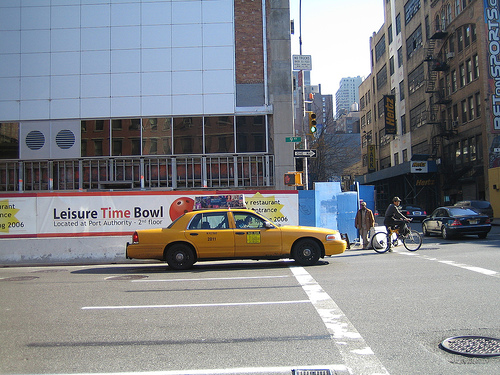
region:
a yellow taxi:
[125, 206, 346, 266]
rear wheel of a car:
[161, 242, 193, 268]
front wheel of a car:
[291, 238, 321, 266]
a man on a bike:
[374, 198, 423, 251]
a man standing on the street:
[352, 201, 374, 246]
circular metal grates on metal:
[19, 120, 80, 158]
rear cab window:
[190, 212, 228, 232]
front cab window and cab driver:
[230, 211, 265, 232]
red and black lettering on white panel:
[50, 206, 162, 228]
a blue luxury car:
[420, 207, 491, 242]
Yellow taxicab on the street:
[122, 205, 347, 271]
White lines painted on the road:
[71, 265, 386, 365]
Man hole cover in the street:
[413, 315, 498, 370]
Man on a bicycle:
[368, 195, 423, 252]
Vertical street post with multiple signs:
[281, 52, 318, 192]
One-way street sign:
[290, 144, 318, 191]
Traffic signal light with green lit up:
[298, 91, 325, 148]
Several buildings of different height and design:
[313, 1, 412, 177]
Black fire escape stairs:
[419, 14, 459, 168]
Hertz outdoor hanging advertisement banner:
[374, 85, 404, 145]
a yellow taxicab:
[115, 199, 380, 273]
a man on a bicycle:
[368, 188, 439, 261]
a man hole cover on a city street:
[434, 315, 499, 362]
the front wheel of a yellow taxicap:
[287, 235, 330, 272]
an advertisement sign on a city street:
[0, 187, 342, 250]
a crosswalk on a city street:
[285, 215, 490, 373]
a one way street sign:
[290, 145, 325, 164]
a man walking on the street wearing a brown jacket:
[350, 197, 375, 259]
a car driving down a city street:
[420, 202, 497, 264]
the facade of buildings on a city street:
[338, 2, 495, 205]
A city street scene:
[6, 0, 498, 362]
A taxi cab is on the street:
[116, 202, 355, 280]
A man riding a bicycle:
[371, 192, 425, 254]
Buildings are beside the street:
[356, 2, 498, 216]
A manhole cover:
[436, 317, 497, 365]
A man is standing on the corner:
[351, 200, 378, 251]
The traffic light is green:
[303, 105, 323, 140]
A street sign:
[289, 142, 321, 162]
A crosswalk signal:
[279, 169, 308, 191]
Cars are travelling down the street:
[405, 197, 495, 243]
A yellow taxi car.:
[118, 192, 348, 267]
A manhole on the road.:
[440, 330, 498, 357]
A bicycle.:
[362, 227, 427, 251]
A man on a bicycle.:
[363, 194, 424, 255]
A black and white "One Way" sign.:
[291, 148, 318, 159]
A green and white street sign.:
[285, 134, 301, 145]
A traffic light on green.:
[304, 110, 319, 136]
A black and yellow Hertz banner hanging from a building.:
[384, 92, 398, 133]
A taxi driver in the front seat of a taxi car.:
[236, 214, 258, 229]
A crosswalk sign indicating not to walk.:
[281, 170, 306, 188]